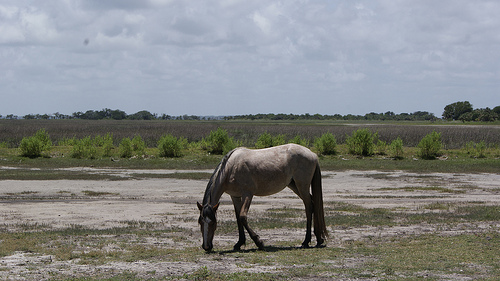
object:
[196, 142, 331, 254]
horse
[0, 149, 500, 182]
grass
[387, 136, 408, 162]
bushes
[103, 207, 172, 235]
dirt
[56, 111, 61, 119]
trees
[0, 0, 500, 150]
background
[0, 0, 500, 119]
sky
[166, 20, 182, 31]
clouds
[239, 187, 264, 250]
legs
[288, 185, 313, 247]
legs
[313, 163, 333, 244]
tail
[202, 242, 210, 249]
nose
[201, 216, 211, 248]
markings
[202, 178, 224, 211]
neck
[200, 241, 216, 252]
mouth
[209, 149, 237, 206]
mane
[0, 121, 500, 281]
field